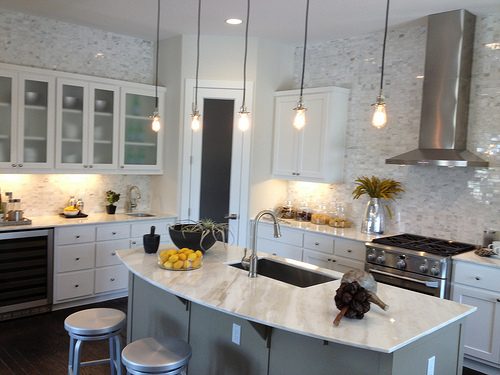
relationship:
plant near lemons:
[166, 217, 236, 250] [157, 246, 202, 270]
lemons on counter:
[157, 246, 202, 270] [114, 230, 478, 353]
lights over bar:
[150, 0, 391, 133] [114, 234, 477, 374]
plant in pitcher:
[352, 174, 404, 220] [359, 195, 386, 235]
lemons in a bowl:
[157, 246, 202, 270] [157, 247, 204, 272]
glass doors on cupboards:
[0, 76, 158, 164] [0, 61, 352, 184]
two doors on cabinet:
[272, 93, 329, 181] [271, 86, 351, 186]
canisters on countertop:
[276, 195, 350, 229] [250, 213, 500, 268]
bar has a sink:
[114, 234, 477, 374] [225, 257, 339, 289]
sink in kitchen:
[225, 257, 339, 289] [0, 0, 499, 374]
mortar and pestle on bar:
[142, 224, 162, 253] [114, 234, 477, 374]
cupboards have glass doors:
[0, 61, 352, 184] [0, 76, 158, 164]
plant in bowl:
[166, 217, 236, 250] [168, 222, 222, 253]